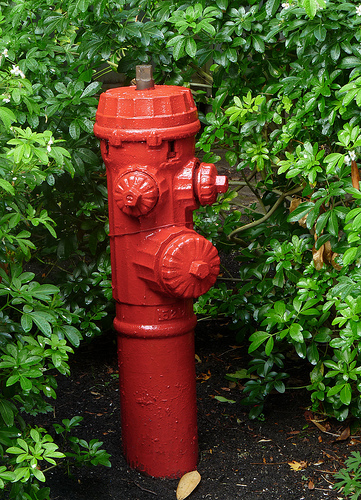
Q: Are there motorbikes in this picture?
A: No, there are no motorbikes.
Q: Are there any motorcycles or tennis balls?
A: No, there are no motorcycles or tennis balls.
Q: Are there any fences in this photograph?
A: No, there are no fences.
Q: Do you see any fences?
A: No, there are no fences.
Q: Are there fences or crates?
A: No, there are no fences or crates.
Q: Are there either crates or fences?
A: No, there are no fences or crates.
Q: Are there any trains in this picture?
A: No, there are no trains.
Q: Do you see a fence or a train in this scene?
A: No, there are no trains or fences.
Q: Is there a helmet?
A: No, there are no helmets.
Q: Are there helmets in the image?
A: No, there are no helmets.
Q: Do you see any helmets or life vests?
A: No, there are no helmets or life vests.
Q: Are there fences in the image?
A: No, there are no fences.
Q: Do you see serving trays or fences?
A: No, there are no fences or serving trays.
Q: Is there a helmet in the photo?
A: No, there are no helmets.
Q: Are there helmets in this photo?
A: No, there are no helmets.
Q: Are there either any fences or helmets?
A: No, there are no helmets or fences.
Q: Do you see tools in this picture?
A: No, there are no tools.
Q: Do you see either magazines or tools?
A: No, there are no tools or magazines.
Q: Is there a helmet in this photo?
A: No, there are no helmets.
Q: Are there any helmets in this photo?
A: No, there are no helmets.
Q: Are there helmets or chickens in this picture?
A: No, there are no helmets or chickens.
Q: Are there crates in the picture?
A: No, there are no crates.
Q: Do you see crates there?
A: No, there are no crates.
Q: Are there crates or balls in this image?
A: No, there are no crates or balls.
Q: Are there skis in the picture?
A: No, there are no skis.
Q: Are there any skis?
A: No, there are no skis.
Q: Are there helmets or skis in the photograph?
A: No, there are no skis or helmets.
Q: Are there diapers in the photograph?
A: No, there are no diapers.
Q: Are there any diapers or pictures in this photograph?
A: No, there are no diapers or pictures.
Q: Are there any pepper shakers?
A: No, there are no pepper shakers.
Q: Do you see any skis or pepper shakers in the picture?
A: No, there are no pepper shakers or skis.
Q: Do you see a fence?
A: No, there are no fences.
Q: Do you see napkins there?
A: No, there are no napkins.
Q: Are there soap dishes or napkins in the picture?
A: No, there are no napkins or soap dishes.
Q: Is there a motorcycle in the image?
A: No, there are no motorcycles.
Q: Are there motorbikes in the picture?
A: No, there are no motorbikes.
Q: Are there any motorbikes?
A: No, there are no motorbikes.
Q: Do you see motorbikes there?
A: No, there are no motorbikes.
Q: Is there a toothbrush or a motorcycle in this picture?
A: No, there are no motorcycles or toothbrushes.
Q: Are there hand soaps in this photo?
A: No, there are no hand soaps.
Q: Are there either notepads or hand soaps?
A: No, there are no hand soaps or notepads.